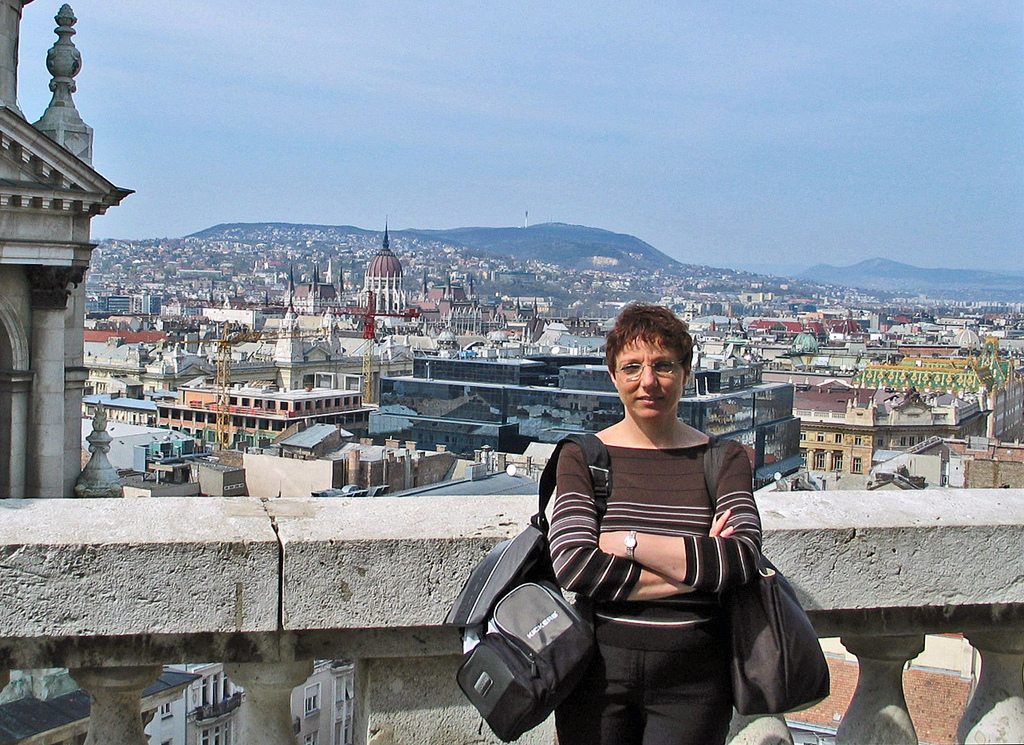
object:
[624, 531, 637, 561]
watch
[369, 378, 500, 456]
wall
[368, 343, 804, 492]
building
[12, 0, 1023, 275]
sky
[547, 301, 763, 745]
woman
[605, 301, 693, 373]
brown hair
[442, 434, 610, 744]
black bag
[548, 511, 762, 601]
arms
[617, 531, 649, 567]
wrist